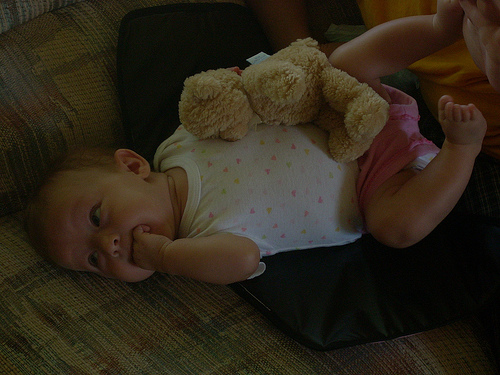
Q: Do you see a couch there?
A: Yes, there is a couch.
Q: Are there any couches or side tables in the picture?
A: Yes, there is a couch.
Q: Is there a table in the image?
A: No, there are no tables.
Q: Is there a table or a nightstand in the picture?
A: No, there are no tables or nightstands.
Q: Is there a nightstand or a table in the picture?
A: No, there are no tables or nightstands.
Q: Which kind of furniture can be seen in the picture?
A: The furniture is a couch.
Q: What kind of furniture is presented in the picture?
A: The furniture is a couch.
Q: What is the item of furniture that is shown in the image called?
A: The piece of furniture is a couch.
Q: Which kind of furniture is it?
A: The piece of furniture is a couch.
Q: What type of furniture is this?
A: This is a couch.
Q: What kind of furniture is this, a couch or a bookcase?
A: This is a couch.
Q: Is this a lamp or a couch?
A: This is a couch.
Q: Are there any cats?
A: No, there are no cats.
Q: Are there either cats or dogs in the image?
A: No, there are no cats or dogs.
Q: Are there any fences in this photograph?
A: No, there are no fences.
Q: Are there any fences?
A: No, there are no fences.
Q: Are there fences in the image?
A: No, there are no fences.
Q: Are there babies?
A: Yes, there is a baby.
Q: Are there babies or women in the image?
A: Yes, there is a baby.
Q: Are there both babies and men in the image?
A: No, there is a baby but no men.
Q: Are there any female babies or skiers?
A: Yes, there is a female baby.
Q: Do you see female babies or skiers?
A: Yes, there is a female baby.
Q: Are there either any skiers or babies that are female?
A: Yes, the baby is female.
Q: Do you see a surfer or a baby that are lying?
A: Yes, the baby is lying.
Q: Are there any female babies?
A: Yes, there is a female baby.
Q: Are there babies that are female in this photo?
A: Yes, there is a female baby.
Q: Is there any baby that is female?
A: Yes, there is a baby that is female.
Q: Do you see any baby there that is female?
A: Yes, there is a baby that is female.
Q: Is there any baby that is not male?
A: Yes, there is a female baby.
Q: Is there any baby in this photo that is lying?
A: Yes, there is a baby that is lying.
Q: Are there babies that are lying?
A: Yes, there is a baby that is lying.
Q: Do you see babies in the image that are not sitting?
A: Yes, there is a baby that is lying .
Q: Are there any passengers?
A: No, there are no passengers.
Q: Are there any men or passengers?
A: No, there are no passengers or men.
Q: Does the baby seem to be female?
A: Yes, the baby is female.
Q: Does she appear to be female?
A: Yes, the baby is female.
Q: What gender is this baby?
A: The baby is female.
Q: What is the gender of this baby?
A: The baby is female.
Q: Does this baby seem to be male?
A: No, the baby is female.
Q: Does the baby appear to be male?
A: No, the baby is female.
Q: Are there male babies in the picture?
A: No, there is a baby but she is female.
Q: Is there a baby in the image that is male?
A: No, there is a baby but she is female.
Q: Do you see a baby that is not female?
A: No, there is a baby but she is female.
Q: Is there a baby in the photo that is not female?
A: No, there is a baby but she is female.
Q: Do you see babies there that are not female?
A: No, there is a baby but she is female.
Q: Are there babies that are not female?
A: No, there is a baby but she is female.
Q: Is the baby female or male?
A: The baby is female.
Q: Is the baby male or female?
A: The baby is female.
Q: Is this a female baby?
A: Yes, this is a female baby.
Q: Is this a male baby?
A: No, this is a female baby.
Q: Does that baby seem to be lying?
A: Yes, the baby is lying.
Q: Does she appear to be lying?
A: Yes, the baby is lying.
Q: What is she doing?
A: The baby is lying.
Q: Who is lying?
A: The baby is lying.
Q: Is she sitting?
A: No, the baby is lying.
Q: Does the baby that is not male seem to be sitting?
A: No, the baby is lying.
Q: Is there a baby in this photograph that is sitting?
A: No, there is a baby but she is lying.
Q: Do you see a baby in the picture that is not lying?
A: No, there is a baby but she is lying.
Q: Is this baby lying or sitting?
A: The baby is lying.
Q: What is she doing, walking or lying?
A: The baby is lying.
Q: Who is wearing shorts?
A: The baby is wearing shorts.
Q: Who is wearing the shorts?
A: The baby is wearing shorts.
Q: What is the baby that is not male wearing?
A: The baby is wearing shorts.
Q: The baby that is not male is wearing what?
A: The baby is wearing shorts.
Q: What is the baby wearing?
A: The baby is wearing shorts.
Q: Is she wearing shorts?
A: Yes, the baby is wearing shorts.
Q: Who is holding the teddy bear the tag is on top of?
A: The baby is holding the teddy bear.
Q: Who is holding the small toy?
A: The baby is holding the teddy bear.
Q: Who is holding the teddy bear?
A: The baby is holding the teddy bear.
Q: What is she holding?
A: The baby is holding the teddy bear.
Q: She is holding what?
A: The baby is holding the teddy bear.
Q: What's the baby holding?
A: The baby is holding the teddy bear.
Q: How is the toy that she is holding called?
A: The toy is a teddy bear.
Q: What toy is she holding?
A: The baby is holding the teddy bear.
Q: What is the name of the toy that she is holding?
A: The toy is a teddy bear.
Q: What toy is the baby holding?
A: The baby is holding the teddy bear.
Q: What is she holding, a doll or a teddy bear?
A: The baby is holding a teddy bear.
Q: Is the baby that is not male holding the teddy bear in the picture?
A: Yes, the baby is holding the teddy bear.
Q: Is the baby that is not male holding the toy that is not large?
A: Yes, the baby is holding the teddy bear.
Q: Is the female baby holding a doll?
A: No, the baby is holding the teddy bear.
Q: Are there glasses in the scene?
A: No, there are no glasses.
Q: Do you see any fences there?
A: No, there are no fences.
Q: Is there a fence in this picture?
A: No, there are no fences.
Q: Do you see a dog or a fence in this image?
A: No, there are no fences or dogs.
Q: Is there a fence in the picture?
A: No, there are no fences.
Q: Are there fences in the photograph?
A: No, there are no fences.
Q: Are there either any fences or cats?
A: No, there are no fences or cats.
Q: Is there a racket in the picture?
A: No, there are no rackets.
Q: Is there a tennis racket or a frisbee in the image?
A: No, there are no rackets or frisbees.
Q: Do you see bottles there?
A: No, there are no bottles.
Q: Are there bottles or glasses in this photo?
A: No, there are no bottles or glasses.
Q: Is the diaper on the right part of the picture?
A: Yes, the diaper is on the right of the image.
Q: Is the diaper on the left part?
A: No, the diaper is on the right of the image.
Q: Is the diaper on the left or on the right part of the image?
A: The diaper is on the right of the image.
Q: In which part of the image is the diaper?
A: The diaper is on the right of the image.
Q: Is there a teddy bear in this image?
A: Yes, there is a teddy bear.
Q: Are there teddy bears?
A: Yes, there is a teddy bear.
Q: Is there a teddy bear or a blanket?
A: Yes, there is a teddy bear.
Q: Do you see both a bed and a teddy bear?
A: No, there is a teddy bear but no beds.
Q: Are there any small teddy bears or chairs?
A: Yes, there is a small teddy bear.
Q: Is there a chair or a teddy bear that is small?
A: Yes, the teddy bear is small.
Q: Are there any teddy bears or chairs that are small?
A: Yes, the teddy bear is small.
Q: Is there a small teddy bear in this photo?
A: Yes, there is a small teddy bear.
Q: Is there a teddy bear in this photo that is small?
A: Yes, there is a teddy bear that is small.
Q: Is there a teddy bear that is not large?
A: Yes, there is a small teddy bear.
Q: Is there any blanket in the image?
A: No, there are no blankets.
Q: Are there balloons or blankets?
A: No, there are no blankets or balloons.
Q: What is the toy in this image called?
A: The toy is a teddy bear.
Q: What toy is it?
A: The toy is a teddy bear.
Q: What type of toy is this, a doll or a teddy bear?
A: This is a teddy bear.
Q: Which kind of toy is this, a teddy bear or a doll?
A: This is a teddy bear.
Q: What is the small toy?
A: The toy is a teddy bear.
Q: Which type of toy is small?
A: The toy is a teddy bear.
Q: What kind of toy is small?
A: The toy is a teddy bear.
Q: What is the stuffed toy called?
A: The toy is a teddy bear.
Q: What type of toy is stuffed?
A: The toy is a teddy bear.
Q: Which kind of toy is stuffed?
A: The toy is a teddy bear.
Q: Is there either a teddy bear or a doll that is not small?
A: No, there is a teddy bear but it is small.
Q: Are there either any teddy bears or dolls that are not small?
A: No, there is a teddy bear but it is small.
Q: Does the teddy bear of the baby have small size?
A: Yes, the teddy bear is small.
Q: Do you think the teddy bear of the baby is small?
A: Yes, the teddy bear is small.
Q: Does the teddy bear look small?
A: Yes, the teddy bear is small.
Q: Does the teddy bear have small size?
A: Yes, the teddy bear is small.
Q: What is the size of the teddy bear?
A: The teddy bear is small.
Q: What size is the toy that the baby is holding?
A: The teddy bear is small.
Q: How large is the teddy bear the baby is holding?
A: The teddy bear is small.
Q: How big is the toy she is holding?
A: The teddy bear is small.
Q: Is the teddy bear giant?
A: No, the teddy bear is small.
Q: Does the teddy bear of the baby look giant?
A: No, the teddy bear is small.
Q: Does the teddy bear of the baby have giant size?
A: No, the teddy bear is small.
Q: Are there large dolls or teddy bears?
A: No, there is a teddy bear but it is small.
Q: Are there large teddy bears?
A: No, there is a teddy bear but it is small.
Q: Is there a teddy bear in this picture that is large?
A: No, there is a teddy bear but it is small.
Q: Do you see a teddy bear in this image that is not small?
A: No, there is a teddy bear but it is small.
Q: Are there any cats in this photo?
A: No, there are no cats.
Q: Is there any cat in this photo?
A: No, there are no cats.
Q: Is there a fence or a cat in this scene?
A: No, there are no cats or fences.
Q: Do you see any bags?
A: No, there are no bags.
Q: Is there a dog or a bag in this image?
A: No, there are no bags or dogs.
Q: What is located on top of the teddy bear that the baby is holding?
A: The tag is on top of the teddy bear.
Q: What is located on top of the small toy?
A: The tag is on top of the teddy bear.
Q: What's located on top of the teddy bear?
A: The tag is on top of the teddy bear.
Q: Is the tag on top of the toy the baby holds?
A: Yes, the tag is on top of the teddy bear.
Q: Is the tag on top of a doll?
A: No, the tag is on top of the teddy bear.